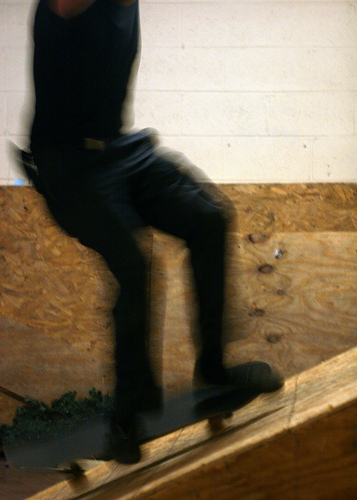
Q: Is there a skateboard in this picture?
A: Yes, there is a skateboard.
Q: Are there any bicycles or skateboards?
A: Yes, there is a skateboard.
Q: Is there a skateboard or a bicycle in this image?
A: Yes, there is a skateboard.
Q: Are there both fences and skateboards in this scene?
A: No, there is a skateboard but no fences.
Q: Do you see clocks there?
A: No, there are no clocks.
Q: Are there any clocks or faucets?
A: No, there are no clocks or faucets.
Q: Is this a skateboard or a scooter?
A: This is a skateboard.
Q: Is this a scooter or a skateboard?
A: This is a skateboard.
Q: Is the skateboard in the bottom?
A: Yes, the skateboard is in the bottom of the image.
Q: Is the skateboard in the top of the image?
A: No, the skateboard is in the bottom of the image.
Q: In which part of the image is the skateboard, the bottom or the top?
A: The skateboard is in the bottom of the image.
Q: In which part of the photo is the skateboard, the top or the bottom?
A: The skateboard is in the bottom of the image.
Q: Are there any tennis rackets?
A: No, there are no tennis rackets.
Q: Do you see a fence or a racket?
A: No, there are no rackets or fences.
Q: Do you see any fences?
A: No, there are no fences.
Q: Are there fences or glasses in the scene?
A: No, there are no fences or glasses.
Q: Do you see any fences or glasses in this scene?
A: No, there are no fences or glasses.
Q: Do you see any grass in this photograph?
A: Yes, there is grass.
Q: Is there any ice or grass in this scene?
A: Yes, there is grass.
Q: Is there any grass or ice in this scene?
A: Yes, there is grass.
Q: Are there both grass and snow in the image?
A: No, there is grass but no snow.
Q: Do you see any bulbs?
A: No, there are no bulbs.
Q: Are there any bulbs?
A: No, there are no bulbs.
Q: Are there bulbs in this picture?
A: No, there are no bulbs.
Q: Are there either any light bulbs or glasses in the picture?
A: No, there are no light bulbs or glasses.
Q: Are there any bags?
A: No, there are no bags.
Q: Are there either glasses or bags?
A: No, there are no bags or glasses.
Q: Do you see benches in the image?
A: Yes, there is a bench.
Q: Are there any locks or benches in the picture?
A: Yes, there is a bench.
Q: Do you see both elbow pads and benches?
A: No, there is a bench but no elbow pads.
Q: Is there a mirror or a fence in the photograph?
A: No, there are no fences or mirrors.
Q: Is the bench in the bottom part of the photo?
A: Yes, the bench is in the bottom of the image.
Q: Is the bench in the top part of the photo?
A: No, the bench is in the bottom of the image.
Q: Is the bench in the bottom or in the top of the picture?
A: The bench is in the bottom of the image.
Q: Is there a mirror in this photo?
A: No, there are no mirrors.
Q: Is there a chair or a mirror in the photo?
A: No, there are no mirrors or chairs.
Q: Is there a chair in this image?
A: No, there are no chairs.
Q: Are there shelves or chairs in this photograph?
A: No, there are no chairs or shelves.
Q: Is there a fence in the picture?
A: No, there are no fences.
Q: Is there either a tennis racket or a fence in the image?
A: No, there are no fences or rackets.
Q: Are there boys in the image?
A: No, there are no boys.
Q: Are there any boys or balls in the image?
A: No, there are no boys or balls.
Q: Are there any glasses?
A: No, there are no glasses.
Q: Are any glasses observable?
A: No, there are no glasses.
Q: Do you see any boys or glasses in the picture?
A: No, there are no glasses or boys.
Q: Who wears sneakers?
A: The man wears sneakers.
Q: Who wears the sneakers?
A: The man wears sneakers.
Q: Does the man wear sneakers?
A: Yes, the man wears sneakers.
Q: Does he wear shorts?
A: No, the man wears sneakers.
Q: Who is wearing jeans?
A: The man is wearing jeans.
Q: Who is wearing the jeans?
A: The man is wearing jeans.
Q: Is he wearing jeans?
A: Yes, the man is wearing jeans.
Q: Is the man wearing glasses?
A: No, the man is wearing jeans.